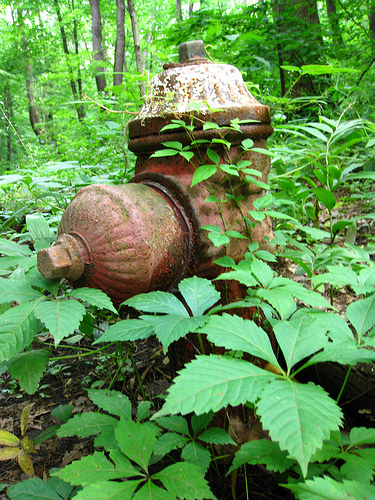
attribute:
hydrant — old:
[34, 26, 314, 313]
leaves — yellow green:
[3, 409, 39, 477]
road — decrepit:
[39, 41, 321, 353]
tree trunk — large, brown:
[264, 0, 337, 126]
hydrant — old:
[62, 61, 283, 373]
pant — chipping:
[141, 64, 253, 114]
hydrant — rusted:
[43, 38, 281, 343]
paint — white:
[169, 66, 243, 104]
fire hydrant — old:
[40, 36, 283, 323]